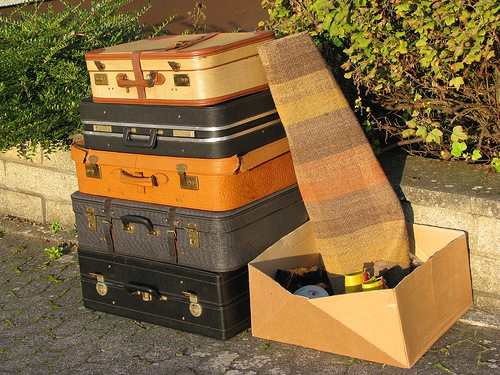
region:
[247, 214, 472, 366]
a cardboard box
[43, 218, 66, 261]
weeds growing on the road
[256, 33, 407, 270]
stripe pattern blanket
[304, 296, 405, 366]
bend on the box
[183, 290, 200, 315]
brass case lock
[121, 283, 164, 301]
the handle is black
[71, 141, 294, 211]
an orange suitcase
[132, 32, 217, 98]
a brown leather strap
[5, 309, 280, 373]
cracks on the asphalt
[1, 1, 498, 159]
bushes behind the suit case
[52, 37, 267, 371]
a stack of suitcases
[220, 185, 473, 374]
a cardboard box next to suitcases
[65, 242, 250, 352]
a black suitcase on bottom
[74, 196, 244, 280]
a gray suitcase on black suitcase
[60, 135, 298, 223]
an orange suitcase in the middle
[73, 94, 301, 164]
a black suitcase on top of orange suitcase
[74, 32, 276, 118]
a brown and tan suitcase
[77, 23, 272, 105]
a brown and tan suitcase on top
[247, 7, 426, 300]
a rolled up piece of cloth in box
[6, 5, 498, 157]
green shrubs around suitcases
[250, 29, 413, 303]
Roll of striped fabric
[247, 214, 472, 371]
Light brown cardboard box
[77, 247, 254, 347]
Black suitcase at the bottom of the stack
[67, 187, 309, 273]
Large gray suitcase 2nd from the bottom of the stack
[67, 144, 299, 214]
Gold-colored suitcase, 3rd in a stack of 5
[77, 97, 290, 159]
Gray and black suitcase, 2nd from the top of a stack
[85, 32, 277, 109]
Small light brown suitcase at the top of a stack of 5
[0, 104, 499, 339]
Stone retaining wall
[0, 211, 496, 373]
A footpath made of pavers, with weeds growing in between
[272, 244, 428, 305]
Other supplies in a cardboard box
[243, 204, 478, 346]
a box on the ground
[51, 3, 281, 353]
the suitcases are stacked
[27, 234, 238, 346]
the bottom suitcase is black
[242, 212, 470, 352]
the box is brown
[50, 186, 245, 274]
the second suitcase is grey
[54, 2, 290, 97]
the top suitcase is two toned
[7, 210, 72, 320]
grass is growing between the cement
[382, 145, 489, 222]
the ledge is grey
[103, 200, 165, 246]
the handle is black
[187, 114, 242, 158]
the light is reflected on the suitcase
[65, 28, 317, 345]
a pile of vintage suitcases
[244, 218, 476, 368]
a cardboard box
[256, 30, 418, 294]
an earthtone rug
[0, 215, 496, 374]
a patio with weeds growing on it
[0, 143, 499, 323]
a beige masonry wall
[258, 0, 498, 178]
an ivy-like shrub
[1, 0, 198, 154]
a shrub with small leaves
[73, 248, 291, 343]
black vintage suitcase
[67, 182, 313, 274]
grey vintage suitcase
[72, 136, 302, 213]
tan vintage suitcase that is torn